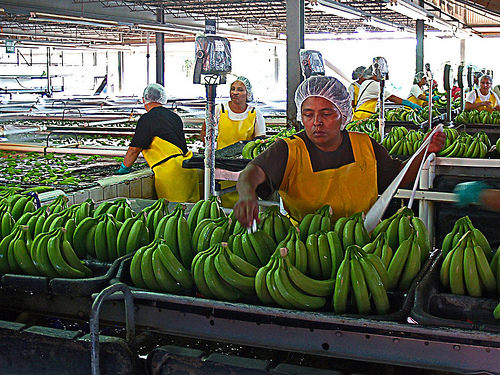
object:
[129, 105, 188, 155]
shirt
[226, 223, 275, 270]
bananas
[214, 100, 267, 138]
undershirt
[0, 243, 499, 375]
cart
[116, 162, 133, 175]
glove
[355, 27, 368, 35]
lights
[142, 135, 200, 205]
apron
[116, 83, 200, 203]
person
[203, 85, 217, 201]
pole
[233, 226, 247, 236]
stem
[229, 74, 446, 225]
man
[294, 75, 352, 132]
hairnet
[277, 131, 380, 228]
apron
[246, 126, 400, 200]
shirt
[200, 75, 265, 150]
woman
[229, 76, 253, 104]
head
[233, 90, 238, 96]
nose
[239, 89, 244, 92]
eye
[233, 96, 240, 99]
mouth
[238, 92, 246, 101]
cheek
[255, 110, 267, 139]
arm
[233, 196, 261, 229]
hand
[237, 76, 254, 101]
bag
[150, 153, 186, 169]
strap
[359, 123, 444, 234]
paper